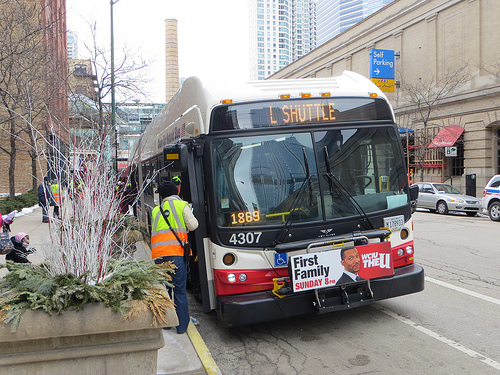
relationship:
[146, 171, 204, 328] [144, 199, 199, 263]
person wearing vest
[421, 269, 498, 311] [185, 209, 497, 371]
white line painted on street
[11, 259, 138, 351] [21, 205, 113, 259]
planter on sidewalk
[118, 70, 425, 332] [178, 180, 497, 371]
bus on street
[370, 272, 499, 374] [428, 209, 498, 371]
two whitelines on street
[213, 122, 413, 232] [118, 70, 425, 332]
window in front of bus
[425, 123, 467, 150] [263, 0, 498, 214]
awning on building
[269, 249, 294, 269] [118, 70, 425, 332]
sign on bus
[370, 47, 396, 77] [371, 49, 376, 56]
sign has letter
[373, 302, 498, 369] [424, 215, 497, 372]
stripe on road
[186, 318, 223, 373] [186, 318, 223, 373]
yellow paint on yellow paint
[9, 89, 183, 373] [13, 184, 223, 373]
plants on sidewalk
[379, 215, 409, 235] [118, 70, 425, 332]
licence plate on bus